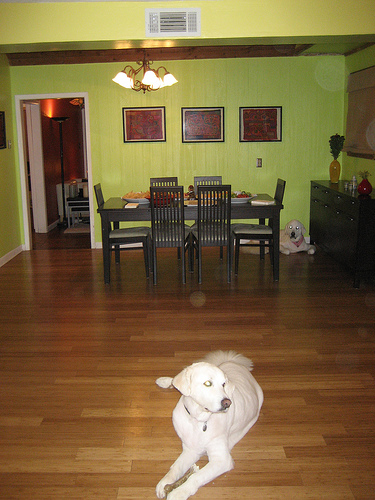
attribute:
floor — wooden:
[2, 249, 373, 498]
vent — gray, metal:
[144, 13, 201, 35]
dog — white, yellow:
[155, 349, 264, 499]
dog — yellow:
[242, 221, 318, 257]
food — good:
[126, 190, 258, 213]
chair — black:
[92, 183, 150, 282]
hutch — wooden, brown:
[308, 180, 372, 288]